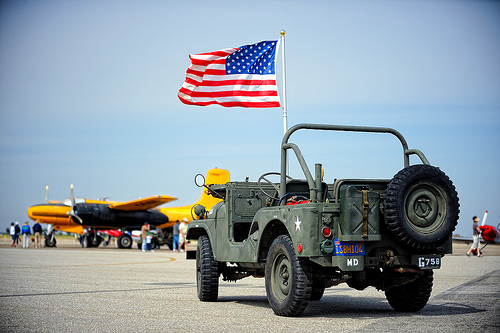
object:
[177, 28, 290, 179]
flag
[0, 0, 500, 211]
sky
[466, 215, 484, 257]
person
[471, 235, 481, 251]
pants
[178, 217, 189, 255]
man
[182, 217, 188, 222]
hat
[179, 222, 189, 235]
shirt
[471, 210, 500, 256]
airplane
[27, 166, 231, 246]
airplane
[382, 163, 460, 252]
tire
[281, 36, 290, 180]
flag pole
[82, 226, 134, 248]
landing gear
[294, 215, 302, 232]
star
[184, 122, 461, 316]
army jeep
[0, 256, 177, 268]
line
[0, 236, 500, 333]
runway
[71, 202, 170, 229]
black engine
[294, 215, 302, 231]
design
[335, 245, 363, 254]
lettering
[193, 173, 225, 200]
mirror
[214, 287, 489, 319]
shadow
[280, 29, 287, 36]
ball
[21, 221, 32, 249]
people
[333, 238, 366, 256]
license plate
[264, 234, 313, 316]
tire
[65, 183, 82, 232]
propeller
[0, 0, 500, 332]
wind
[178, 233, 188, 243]
pants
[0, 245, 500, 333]
ground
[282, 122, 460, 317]
back